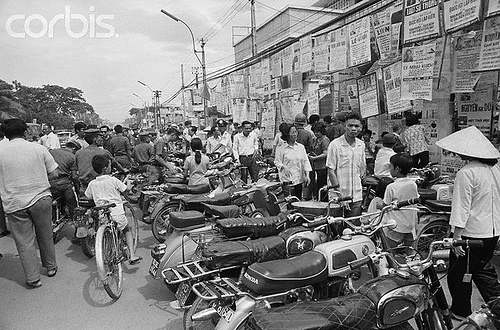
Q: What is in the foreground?
A: Bikes.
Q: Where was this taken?
A: China.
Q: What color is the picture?
A: Black and white.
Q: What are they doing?
A: Talking.